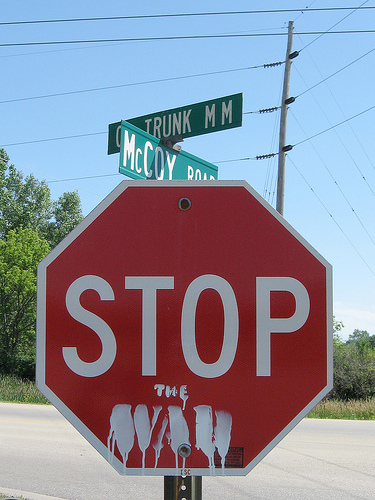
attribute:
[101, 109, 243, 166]
sign — green, street, stop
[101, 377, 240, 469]
paint — white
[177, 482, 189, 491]
hole — stop sign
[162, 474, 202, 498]
pole — metal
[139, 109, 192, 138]
lettering — white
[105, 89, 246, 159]
sign — green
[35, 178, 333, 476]
outer edge — white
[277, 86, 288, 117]
pole — silver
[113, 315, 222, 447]
sign — red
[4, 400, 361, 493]
road — paved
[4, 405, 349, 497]
road — paved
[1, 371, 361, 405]
grass — green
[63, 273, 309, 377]
lettering — white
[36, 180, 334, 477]
sign — red, eight sided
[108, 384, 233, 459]
wording — white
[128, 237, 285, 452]
sign — red